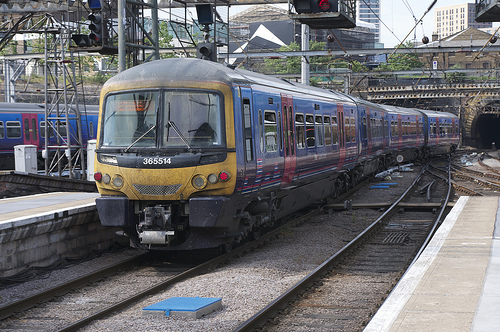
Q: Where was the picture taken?
A: At the train station.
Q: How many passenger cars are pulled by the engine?
A: Three.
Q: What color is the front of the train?
A: Yellow.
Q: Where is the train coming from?
A: A tunnel.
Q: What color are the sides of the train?
A: Blue and red.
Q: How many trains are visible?
A: Two.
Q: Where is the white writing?
A: Under the windshield.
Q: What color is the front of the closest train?
A: Yellow.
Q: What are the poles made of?
A: Metal.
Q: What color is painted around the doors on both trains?
A: Red.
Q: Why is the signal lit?
A: To direct train traffic.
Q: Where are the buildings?
A: Background.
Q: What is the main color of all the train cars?
A: Blue.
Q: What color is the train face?
A: The train face is yellow.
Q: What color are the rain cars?
A: The train car is blue and red.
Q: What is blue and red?
A: The train car is blue and red.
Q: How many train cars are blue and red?
A: There are 4 blue and red train cars.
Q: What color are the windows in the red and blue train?
A: The windows are clear.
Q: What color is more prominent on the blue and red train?
A: The color blue.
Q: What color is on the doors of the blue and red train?
A: The doors are red.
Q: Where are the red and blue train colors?
A: On the side of the train.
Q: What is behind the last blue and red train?
A: There is a tunnel behind the last blue and red train.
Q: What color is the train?
A: Yellow and red.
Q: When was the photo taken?
A: During the daytime.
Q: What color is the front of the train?
A: Yellow.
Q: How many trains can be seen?
A: Two.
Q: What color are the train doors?
A: Red.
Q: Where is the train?
A: On the tracks.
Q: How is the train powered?
A: By electricity.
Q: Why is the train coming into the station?
A: To pick up and drop off passengers.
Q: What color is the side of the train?
A: Blue.